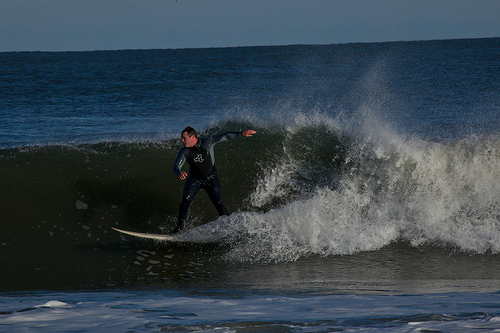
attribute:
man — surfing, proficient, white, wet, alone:
[169, 126, 260, 237]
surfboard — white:
[106, 225, 175, 246]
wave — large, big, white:
[1, 112, 500, 271]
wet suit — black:
[172, 132, 244, 226]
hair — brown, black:
[181, 126, 199, 137]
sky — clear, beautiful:
[2, 3, 499, 54]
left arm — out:
[209, 125, 260, 144]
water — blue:
[1, 38, 500, 332]